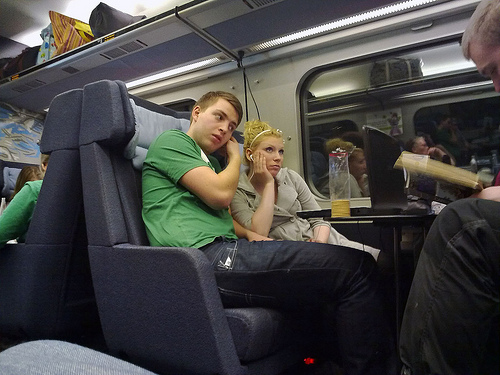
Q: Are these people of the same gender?
A: No, they are both male and female.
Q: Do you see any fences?
A: No, there are no fences.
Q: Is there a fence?
A: No, there are no fences.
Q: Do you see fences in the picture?
A: No, there are no fences.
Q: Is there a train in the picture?
A: Yes, there is a train.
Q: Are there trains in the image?
A: Yes, there is a train.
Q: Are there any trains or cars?
A: Yes, there is a train.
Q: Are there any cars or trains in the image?
A: Yes, there is a train.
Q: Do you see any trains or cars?
A: Yes, there is a train.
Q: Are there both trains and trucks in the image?
A: No, there is a train but no trucks.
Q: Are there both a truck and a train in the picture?
A: No, there is a train but no trucks.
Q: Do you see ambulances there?
A: No, there are no ambulances.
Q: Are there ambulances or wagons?
A: No, there are no ambulances or wagons.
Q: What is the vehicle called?
A: The vehicle is a train.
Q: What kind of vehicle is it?
A: The vehicle is a train.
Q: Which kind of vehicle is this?
A: This is a train.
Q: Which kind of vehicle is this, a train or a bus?
A: This is a train.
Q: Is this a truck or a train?
A: This is a train.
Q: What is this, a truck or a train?
A: This is a train.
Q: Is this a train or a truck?
A: This is a train.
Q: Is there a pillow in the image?
A: No, there are no pillows.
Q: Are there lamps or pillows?
A: No, there are no pillows or lamps.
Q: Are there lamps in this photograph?
A: No, there are no lamps.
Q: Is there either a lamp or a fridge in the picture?
A: No, there are no lamps or refrigerators.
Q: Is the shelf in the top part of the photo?
A: Yes, the shelf is in the top of the image.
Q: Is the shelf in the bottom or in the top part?
A: The shelf is in the top of the image.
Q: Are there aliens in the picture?
A: No, there are no aliens.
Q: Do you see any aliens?
A: No, there are no aliens.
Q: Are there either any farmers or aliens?
A: No, there are no aliens or farmers.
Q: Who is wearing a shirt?
A: The guy is wearing a shirt.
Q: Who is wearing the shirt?
A: The guy is wearing a shirt.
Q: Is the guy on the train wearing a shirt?
A: Yes, the guy is wearing a shirt.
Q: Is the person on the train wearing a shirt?
A: Yes, the guy is wearing a shirt.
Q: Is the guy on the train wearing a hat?
A: No, the guy is wearing a shirt.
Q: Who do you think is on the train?
A: The guy is on the train.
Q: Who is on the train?
A: The guy is on the train.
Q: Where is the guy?
A: The guy is on the train.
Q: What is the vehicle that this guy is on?
A: The vehicle is a train.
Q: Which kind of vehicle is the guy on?
A: The guy is on the train.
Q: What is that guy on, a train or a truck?
A: The guy is on a train.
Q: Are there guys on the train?
A: Yes, there is a guy on the train.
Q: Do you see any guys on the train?
A: Yes, there is a guy on the train.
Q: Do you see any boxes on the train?
A: No, there is a guy on the train.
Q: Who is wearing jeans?
A: The guy is wearing jeans.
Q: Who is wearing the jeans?
A: The guy is wearing jeans.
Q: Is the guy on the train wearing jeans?
A: Yes, the guy is wearing jeans.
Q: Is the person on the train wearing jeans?
A: Yes, the guy is wearing jeans.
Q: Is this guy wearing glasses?
A: No, the guy is wearing jeans.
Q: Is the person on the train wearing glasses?
A: No, the guy is wearing jeans.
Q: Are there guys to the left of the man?
A: Yes, there is a guy to the left of the man.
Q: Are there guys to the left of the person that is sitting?
A: Yes, there is a guy to the left of the man.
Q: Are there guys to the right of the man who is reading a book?
A: No, the guy is to the left of the man.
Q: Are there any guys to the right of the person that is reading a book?
A: No, the guy is to the left of the man.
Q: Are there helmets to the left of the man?
A: No, there is a guy to the left of the man.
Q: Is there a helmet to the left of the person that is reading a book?
A: No, there is a guy to the left of the man.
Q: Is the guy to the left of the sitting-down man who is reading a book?
A: Yes, the guy is to the left of the man.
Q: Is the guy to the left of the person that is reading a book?
A: Yes, the guy is to the left of the man.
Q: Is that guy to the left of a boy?
A: No, the guy is to the left of the man.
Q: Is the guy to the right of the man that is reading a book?
A: No, the guy is to the left of the man.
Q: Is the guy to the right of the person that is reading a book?
A: No, the guy is to the left of the man.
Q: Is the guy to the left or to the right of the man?
A: The guy is to the left of the man.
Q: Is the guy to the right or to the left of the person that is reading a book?
A: The guy is to the left of the man.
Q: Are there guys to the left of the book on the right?
A: Yes, there is a guy to the left of the book.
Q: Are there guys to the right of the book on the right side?
A: No, the guy is to the left of the book.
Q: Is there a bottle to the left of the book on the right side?
A: No, there is a guy to the left of the book.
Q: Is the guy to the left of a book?
A: Yes, the guy is to the left of a book.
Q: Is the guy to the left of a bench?
A: No, the guy is to the left of a book.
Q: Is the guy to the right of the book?
A: No, the guy is to the left of the book.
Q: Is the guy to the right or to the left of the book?
A: The guy is to the left of the book.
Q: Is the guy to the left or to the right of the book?
A: The guy is to the left of the book.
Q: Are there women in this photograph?
A: Yes, there is a woman.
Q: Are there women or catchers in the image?
A: Yes, there is a woman.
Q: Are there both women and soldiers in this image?
A: No, there is a woman but no soldiers.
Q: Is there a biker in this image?
A: No, there are no bikers.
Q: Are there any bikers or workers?
A: No, there are no bikers or workers.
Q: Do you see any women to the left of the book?
A: Yes, there is a woman to the left of the book.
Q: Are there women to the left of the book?
A: Yes, there is a woman to the left of the book.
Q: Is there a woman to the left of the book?
A: Yes, there is a woman to the left of the book.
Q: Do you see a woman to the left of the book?
A: Yes, there is a woman to the left of the book.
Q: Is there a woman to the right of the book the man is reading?
A: No, the woman is to the left of the book.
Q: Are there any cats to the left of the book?
A: No, there is a woman to the left of the book.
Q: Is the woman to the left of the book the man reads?
A: Yes, the woman is to the left of the book.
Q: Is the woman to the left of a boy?
A: No, the woman is to the left of the book.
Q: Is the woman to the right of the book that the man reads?
A: No, the woman is to the left of the book.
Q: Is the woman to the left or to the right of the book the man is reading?
A: The woman is to the left of the book.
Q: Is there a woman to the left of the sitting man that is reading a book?
A: Yes, there is a woman to the left of the man.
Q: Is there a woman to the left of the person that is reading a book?
A: Yes, there is a woman to the left of the man.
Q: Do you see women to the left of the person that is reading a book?
A: Yes, there is a woman to the left of the man.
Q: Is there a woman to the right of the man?
A: No, the woman is to the left of the man.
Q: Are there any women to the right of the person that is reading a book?
A: No, the woman is to the left of the man.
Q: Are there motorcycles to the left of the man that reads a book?
A: No, there is a woman to the left of the man.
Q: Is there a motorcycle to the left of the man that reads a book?
A: No, there is a woman to the left of the man.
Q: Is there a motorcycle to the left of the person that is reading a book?
A: No, there is a woman to the left of the man.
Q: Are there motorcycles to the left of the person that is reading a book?
A: No, there is a woman to the left of the man.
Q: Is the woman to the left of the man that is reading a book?
A: Yes, the woman is to the left of the man.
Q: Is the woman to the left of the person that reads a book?
A: Yes, the woman is to the left of the man.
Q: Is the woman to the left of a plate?
A: No, the woman is to the left of the man.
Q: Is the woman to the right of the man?
A: No, the woman is to the left of the man.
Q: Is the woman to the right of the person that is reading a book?
A: No, the woman is to the left of the man.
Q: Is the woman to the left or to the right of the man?
A: The woman is to the left of the man.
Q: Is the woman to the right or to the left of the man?
A: The woman is to the left of the man.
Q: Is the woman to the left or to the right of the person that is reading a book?
A: The woman is to the left of the man.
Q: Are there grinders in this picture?
A: No, there are no grinders.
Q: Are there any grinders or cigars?
A: No, there are no grinders or cigars.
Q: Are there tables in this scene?
A: Yes, there is a table.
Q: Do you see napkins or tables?
A: Yes, there is a table.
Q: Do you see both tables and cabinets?
A: No, there is a table but no cabinets.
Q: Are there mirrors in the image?
A: No, there are no mirrors.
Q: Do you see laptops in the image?
A: Yes, there is a laptop.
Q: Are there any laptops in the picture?
A: Yes, there is a laptop.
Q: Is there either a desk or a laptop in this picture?
A: Yes, there is a laptop.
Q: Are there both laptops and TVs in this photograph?
A: No, there is a laptop but no televisions.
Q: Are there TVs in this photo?
A: No, there are no tvs.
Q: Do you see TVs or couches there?
A: No, there are no TVs or couches.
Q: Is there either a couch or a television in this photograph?
A: No, there are no televisions or couches.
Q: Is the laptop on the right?
A: Yes, the laptop is on the right of the image.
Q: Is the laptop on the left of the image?
A: No, the laptop is on the right of the image.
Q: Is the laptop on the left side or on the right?
A: The laptop is on the right of the image.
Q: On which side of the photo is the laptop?
A: The laptop is on the right of the image.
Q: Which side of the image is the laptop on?
A: The laptop is on the right of the image.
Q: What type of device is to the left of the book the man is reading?
A: The device is a laptop.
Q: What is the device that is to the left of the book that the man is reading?
A: The device is a laptop.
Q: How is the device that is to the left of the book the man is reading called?
A: The device is a laptop.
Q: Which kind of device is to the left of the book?
A: The device is a laptop.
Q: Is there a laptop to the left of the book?
A: Yes, there is a laptop to the left of the book.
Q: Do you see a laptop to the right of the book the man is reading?
A: No, the laptop is to the left of the book.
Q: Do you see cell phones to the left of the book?
A: No, there is a laptop to the left of the book.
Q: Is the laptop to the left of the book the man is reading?
A: Yes, the laptop is to the left of the book.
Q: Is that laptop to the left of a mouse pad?
A: No, the laptop is to the left of the book.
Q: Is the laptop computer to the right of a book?
A: No, the laptop computer is to the left of a book.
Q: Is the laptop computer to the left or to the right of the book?
A: The laptop computer is to the left of the book.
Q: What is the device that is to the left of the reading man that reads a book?
A: The device is a laptop.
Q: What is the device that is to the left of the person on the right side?
A: The device is a laptop.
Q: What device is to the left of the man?
A: The device is a laptop.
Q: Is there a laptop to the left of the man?
A: Yes, there is a laptop to the left of the man.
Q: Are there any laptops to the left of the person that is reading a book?
A: Yes, there is a laptop to the left of the man.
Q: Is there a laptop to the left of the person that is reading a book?
A: Yes, there is a laptop to the left of the man.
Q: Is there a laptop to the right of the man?
A: No, the laptop is to the left of the man.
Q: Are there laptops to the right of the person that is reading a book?
A: No, the laptop is to the left of the man.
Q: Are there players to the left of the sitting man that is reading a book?
A: No, there is a laptop to the left of the man.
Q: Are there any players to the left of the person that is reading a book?
A: No, there is a laptop to the left of the man.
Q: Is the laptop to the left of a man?
A: Yes, the laptop is to the left of a man.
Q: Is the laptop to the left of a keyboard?
A: No, the laptop is to the left of a man.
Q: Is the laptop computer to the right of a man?
A: No, the laptop computer is to the left of a man.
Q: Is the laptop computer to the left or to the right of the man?
A: The laptop computer is to the left of the man.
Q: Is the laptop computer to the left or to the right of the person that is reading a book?
A: The laptop computer is to the left of the man.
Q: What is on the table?
A: The laptop is on the table.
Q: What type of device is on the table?
A: The device is a laptop.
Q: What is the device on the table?
A: The device is a laptop.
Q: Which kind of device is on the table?
A: The device is a laptop.